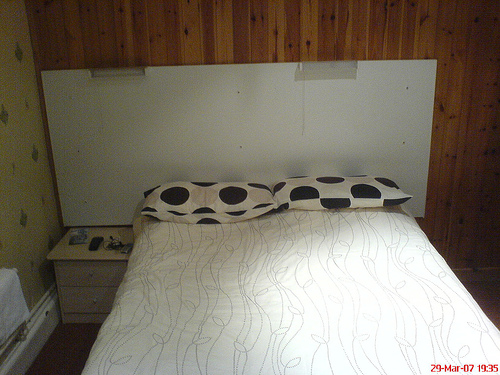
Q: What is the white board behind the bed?
A: A headboard.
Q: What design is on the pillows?
A: Dots.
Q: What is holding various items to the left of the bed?
A: Night stand.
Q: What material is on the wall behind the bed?
A: Wood.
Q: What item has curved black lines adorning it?
A: The bedspread.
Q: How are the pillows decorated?
A: Polka dots.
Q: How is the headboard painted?
A: White.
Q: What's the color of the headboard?
A: White.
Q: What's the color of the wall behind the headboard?
A: Brown.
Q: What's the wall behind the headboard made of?
A: Wood.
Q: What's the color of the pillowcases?
A: Black and white.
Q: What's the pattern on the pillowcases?
A: Polka dots.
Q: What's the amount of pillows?
A: Two.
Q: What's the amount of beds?
A: One.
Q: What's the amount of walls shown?
A: Two.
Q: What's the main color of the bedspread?
A: White.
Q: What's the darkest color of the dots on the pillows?
A: Black.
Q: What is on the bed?
A: Pillows.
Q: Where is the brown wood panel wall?
A: Behind the bed.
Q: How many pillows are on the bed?
A: 2.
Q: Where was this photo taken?
A: In a bedroom.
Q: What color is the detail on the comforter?
A: Black.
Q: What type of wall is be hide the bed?
A: Wood.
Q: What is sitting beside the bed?
A: A nightstand.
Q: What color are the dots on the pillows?
A: Black.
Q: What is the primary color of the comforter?
A: White.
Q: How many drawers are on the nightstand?
A: 2.